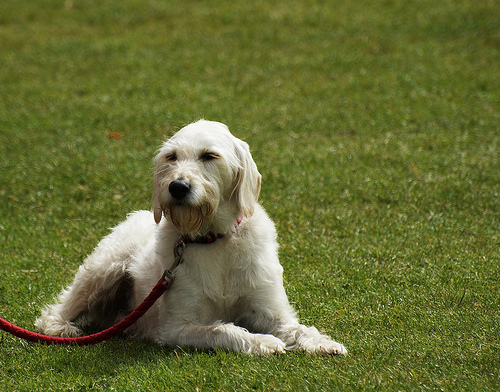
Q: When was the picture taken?
A: Daytime.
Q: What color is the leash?
A: Red.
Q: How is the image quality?
A: Clear.